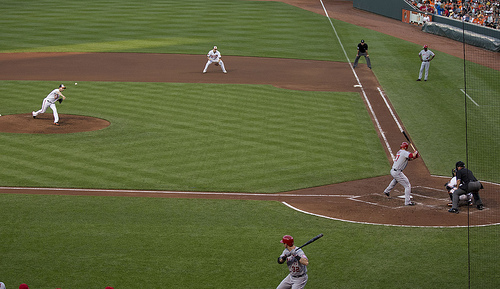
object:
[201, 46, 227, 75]
man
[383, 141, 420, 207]
man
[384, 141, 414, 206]
uniform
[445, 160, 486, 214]
umpire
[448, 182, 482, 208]
pants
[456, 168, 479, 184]
shirt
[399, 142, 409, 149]
helmet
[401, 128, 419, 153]
bat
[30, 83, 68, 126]
pitcher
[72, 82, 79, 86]
ball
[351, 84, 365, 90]
base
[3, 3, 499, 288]
field.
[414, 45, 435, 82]
people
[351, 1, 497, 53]
stands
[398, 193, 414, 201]
base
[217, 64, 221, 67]
mitt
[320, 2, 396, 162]
line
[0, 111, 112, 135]
pitcher mound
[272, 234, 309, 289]
man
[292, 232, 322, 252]
bat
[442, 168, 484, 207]
catcher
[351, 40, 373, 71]
umpire